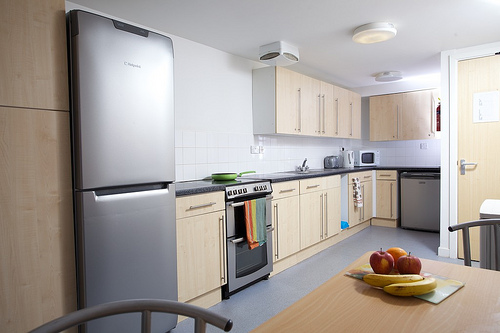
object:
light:
[352, 20, 399, 46]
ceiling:
[71, 0, 499, 92]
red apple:
[370, 249, 393, 276]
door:
[457, 59, 499, 263]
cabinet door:
[179, 212, 230, 297]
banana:
[385, 276, 437, 295]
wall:
[63, 0, 349, 180]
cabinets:
[251, 68, 301, 134]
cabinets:
[300, 76, 322, 136]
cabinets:
[322, 81, 335, 136]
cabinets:
[347, 91, 359, 138]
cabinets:
[370, 89, 400, 143]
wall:
[350, 75, 439, 168]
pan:
[209, 169, 258, 181]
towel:
[237, 200, 277, 249]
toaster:
[319, 155, 338, 173]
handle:
[408, 172, 438, 179]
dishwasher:
[395, 164, 440, 232]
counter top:
[185, 162, 440, 197]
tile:
[183, 148, 196, 163]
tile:
[195, 145, 207, 162]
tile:
[219, 147, 228, 160]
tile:
[183, 165, 197, 180]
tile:
[174, 165, 183, 179]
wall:
[64, 2, 440, 182]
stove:
[221, 178, 274, 298]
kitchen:
[0, 2, 495, 332]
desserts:
[67, 7, 179, 301]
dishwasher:
[401, 172, 441, 229]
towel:
[351, 177, 363, 209]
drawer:
[347, 172, 364, 183]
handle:
[352, 177, 360, 180]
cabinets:
[402, 88, 438, 140]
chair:
[447, 216, 498, 263]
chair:
[11, 299, 230, 332]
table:
[229, 245, 496, 331]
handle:
[457, 161, 478, 167]